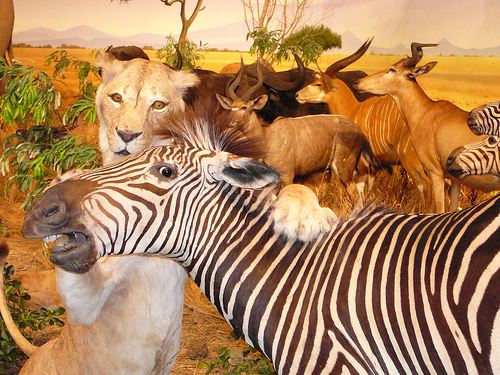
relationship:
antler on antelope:
[244, 56, 267, 98] [214, 47, 374, 210]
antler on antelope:
[224, 55, 245, 99] [214, 47, 374, 210]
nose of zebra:
[19, 192, 74, 234] [24, 107, 499, 369]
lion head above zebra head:
[92, 49, 204, 169] [21, 95, 283, 276]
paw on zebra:
[271, 184, 338, 245] [20, 132, 499, 373]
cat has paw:
[0, 54, 201, 375] [271, 184, 338, 245]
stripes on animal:
[366, 98, 416, 163] [292, 37, 451, 202]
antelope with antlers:
[353, 39, 497, 211] [227, 55, 267, 101]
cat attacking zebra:
[0, 54, 201, 375] [15, 158, 495, 373]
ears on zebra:
[207, 153, 289, 205] [24, 107, 499, 369]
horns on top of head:
[327, 33, 382, 75] [292, 74, 352, 105]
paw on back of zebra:
[271, 184, 338, 245] [24, 107, 499, 369]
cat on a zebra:
[0, 54, 201, 375] [28, 126, 338, 268]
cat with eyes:
[0, 54, 201, 375] [77, 73, 162, 130]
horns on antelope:
[392, 22, 443, 90] [351, 42, 500, 215]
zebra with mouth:
[43, 164, 495, 321] [28, 217, 68, 255]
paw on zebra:
[268, 179, 346, 249] [15, 158, 495, 373]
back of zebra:
[227, 158, 498, 255] [15, 158, 495, 373]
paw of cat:
[268, 179, 346, 249] [0, 54, 201, 375]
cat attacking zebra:
[0, 54, 201, 375] [24, 107, 499, 369]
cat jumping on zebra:
[0, 54, 201, 375] [24, 107, 499, 369]